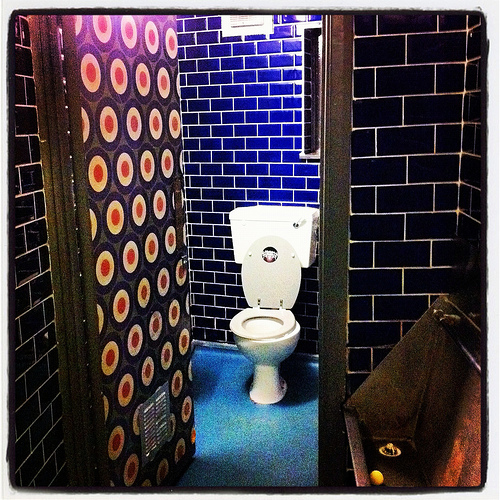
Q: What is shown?
A: A bathroom.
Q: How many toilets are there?
A: One.